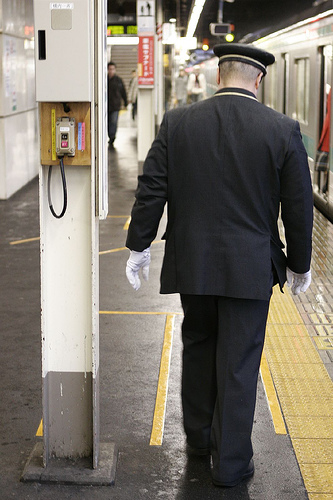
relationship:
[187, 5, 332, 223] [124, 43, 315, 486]
train has conductor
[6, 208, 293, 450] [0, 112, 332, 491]
markings on platform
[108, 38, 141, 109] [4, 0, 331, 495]
stairs leading to subway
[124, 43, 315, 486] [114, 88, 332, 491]
conductor in suit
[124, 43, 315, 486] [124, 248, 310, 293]
conductor in gloves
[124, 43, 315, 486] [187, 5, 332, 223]
conductor for train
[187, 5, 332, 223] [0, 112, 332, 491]
train arrived at platform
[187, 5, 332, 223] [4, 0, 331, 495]
train arrived at station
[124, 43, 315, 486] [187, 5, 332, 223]
conductor walking to train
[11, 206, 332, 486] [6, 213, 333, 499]
zone painted yellow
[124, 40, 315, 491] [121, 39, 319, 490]
conductor in uniform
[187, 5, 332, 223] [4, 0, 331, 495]
train waiting at station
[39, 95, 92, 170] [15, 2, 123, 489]
box on post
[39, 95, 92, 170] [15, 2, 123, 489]
box mounted on post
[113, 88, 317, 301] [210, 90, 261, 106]
jacket with trim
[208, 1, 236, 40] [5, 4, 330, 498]
camera mounted in tunnel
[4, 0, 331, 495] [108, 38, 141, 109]
station has stairway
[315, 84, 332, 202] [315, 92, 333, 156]
passeneger with jacket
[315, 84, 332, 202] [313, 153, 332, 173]
passeneger with skirt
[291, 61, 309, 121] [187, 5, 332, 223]
window on train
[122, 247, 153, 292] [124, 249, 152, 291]
glove on hand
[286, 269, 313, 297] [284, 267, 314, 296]
glove on hand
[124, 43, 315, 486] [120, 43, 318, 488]
man in unifrom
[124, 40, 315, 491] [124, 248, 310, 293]
conductor has gloves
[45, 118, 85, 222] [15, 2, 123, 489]
phone on pole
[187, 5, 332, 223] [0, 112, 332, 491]
train at platform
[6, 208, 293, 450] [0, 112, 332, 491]
markings on floor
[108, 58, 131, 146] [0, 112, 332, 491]
person on platform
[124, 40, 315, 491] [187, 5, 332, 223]
conductor works on train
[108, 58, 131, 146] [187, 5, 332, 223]
person entering train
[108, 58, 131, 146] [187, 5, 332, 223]
person leaving train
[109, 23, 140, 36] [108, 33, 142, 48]
sign above door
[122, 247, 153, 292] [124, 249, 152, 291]
glove covering hand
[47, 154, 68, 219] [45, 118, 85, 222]
cord on telephone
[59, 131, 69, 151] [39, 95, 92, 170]
switch on box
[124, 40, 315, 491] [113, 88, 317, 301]
conductor wearing jacket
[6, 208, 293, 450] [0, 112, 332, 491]
lines marking platform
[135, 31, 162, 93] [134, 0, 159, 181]
sign on pole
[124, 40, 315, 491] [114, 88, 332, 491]
conductor in suit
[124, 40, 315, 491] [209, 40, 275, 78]
conductor wearing hat